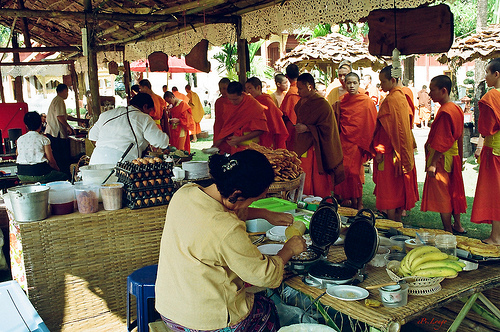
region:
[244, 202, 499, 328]
a table with a woven top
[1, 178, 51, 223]
a metal bucket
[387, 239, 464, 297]
a bunch of bananas on a woven basket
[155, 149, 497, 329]
woman sitting close to table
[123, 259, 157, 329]
a blue plastic stool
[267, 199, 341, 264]
batter being poured into a waffle press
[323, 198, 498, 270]
a line of waffles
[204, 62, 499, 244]
men standing in a line are wearing orange robes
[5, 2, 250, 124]
beams supporting roof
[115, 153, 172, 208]
stacked crates of eggs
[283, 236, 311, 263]
woman pour mix in to the waffle maker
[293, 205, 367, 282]
two waffle makers on the table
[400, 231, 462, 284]
bunch of bananas on the table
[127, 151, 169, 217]
stacks of eggs in their shells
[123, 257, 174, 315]
blue stool next to the woman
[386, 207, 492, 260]
plates on waffle on the table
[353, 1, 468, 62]
sign hanging form the beam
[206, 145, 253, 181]
woman has her hair up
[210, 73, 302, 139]
monks standing in line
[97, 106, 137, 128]
woman has on an apron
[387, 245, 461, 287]
the bananas are sitting in a bowl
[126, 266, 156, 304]
the stool is blue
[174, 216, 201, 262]
the shirt is tan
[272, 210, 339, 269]
the lady is pouring something in the waffle iron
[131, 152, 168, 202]
the eggs are stacked in the egg flats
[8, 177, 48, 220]
the pale is silver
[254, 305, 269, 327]
the skirt is multi color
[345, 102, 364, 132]
the robe thing is orange. don't know what it's called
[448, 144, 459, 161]
the belt around his waist is yellow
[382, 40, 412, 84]
the light is turned off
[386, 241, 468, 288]
banana in a basket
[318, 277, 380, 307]
plate ona table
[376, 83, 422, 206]
man in a orange robe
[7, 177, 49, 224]
a bucket on a table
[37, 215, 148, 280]
a wicker covering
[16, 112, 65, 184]
a person sitting down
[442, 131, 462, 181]
a yellow belt under robe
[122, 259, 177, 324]
a purple stool by lady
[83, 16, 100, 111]
a wooden pole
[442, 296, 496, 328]
wooden legs on table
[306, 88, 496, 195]
The monks wear orange.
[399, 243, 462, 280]
The bananas are light yellow.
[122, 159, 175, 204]
The eggs are brown.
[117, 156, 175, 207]
The eggs are stacked.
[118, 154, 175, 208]
The eggs are stacked on each other.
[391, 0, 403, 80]
The light hangs from the ceiling.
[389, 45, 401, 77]
The light bulb is white.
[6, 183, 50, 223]
The bucket is metal.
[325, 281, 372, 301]
The plate is white.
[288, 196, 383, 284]
The waffle irons are black on the inside.